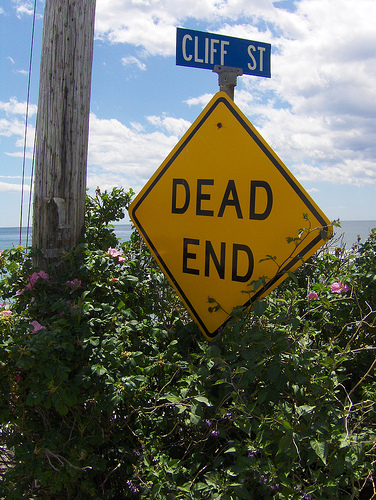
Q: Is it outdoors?
A: Yes, it is outdoors.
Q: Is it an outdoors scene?
A: Yes, it is outdoors.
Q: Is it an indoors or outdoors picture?
A: It is outdoors.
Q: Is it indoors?
A: No, it is outdoors.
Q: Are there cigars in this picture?
A: No, there are no cigars.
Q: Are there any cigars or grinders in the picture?
A: No, there are no cigars or grinders.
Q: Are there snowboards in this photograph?
A: No, there are no snowboards.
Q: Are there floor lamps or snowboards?
A: No, there are no snowboards or floor lamps.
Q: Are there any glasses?
A: No, there are no glasses.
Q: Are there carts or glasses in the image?
A: No, there are no glasses or carts.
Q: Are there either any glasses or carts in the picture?
A: No, there are no glasses or carts.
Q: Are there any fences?
A: No, there are no fences.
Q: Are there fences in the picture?
A: No, there are no fences.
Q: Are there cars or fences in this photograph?
A: No, there are no fences or cars.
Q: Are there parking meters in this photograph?
A: No, there are no parking meters.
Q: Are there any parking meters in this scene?
A: No, there are no parking meters.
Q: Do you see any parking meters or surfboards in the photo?
A: No, there are no parking meters or surfboards.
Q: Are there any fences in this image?
A: No, there are no fences.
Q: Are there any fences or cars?
A: No, there are no fences or cars.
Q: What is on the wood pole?
A: The sign is on the pole.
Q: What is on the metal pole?
A: The sign is on the pole.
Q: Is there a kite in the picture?
A: No, there are no kites.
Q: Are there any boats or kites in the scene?
A: No, there are no kites or boats.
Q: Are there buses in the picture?
A: No, there are no buses.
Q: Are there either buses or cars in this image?
A: No, there are no buses or cars.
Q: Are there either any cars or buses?
A: No, there are no buses or cars.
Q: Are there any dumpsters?
A: No, there are no dumpsters.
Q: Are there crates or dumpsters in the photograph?
A: No, there are no dumpsters or crates.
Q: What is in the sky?
A: The clouds are in the sky.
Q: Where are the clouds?
A: The clouds are in the sky.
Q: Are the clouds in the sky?
A: Yes, the clouds are in the sky.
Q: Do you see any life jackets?
A: No, there are no life jackets.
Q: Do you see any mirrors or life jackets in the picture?
A: No, there are no life jackets or mirrors.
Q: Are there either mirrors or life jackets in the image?
A: No, there are no life jackets or mirrors.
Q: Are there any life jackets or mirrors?
A: No, there are no life jackets or mirrors.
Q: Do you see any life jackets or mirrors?
A: No, there are no life jackets or mirrors.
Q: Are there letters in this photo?
A: Yes, there are letters.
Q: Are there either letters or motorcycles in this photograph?
A: Yes, there are letters.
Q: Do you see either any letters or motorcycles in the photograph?
A: Yes, there are letters.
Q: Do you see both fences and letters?
A: No, there are letters but no fences.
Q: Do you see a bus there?
A: No, there are no buses.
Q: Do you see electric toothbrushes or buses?
A: No, there are no buses or electric toothbrushes.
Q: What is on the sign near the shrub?
A: The letters are on the sign.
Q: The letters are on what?
A: The letters are on the sign.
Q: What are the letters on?
A: The letters are on the sign.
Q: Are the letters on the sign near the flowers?
A: Yes, the letters are on the sign.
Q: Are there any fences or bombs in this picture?
A: No, there are no fences or bombs.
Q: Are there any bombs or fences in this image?
A: No, there are no fences or bombs.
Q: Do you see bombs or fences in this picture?
A: No, there are no fences or bombs.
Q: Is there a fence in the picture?
A: No, there are no fences.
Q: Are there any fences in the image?
A: No, there are no fences.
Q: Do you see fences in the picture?
A: No, there are no fences.